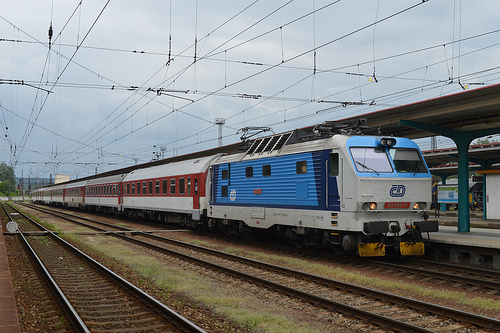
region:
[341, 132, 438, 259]
The front of a gray and blue train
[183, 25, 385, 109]
A collection of criss-crossing wires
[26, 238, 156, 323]
Railroad tracks seen at an angle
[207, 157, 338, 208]
A blue corrugated train car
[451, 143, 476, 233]
A green metal support post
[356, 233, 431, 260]
Black and yellow "mud-flaps"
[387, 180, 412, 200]
A modern, rounded logo in blue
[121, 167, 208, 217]
A red and white train car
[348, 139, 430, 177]
A windshield with two panes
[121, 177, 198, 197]
A row of dark, square windows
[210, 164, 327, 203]
blue paint on train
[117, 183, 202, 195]
red paint on train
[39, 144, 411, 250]
train on train tracks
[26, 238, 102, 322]
train tracks on ground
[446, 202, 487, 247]
train platform beside tracks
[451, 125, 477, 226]
green paint on pole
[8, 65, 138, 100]
light poles above train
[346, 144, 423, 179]
two windows of train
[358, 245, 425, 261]
two yellow pieces on train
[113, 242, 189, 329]
grass growing between tracks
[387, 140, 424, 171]
window on passenger train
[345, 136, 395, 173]
window on passenger train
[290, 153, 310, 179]
window on passenger train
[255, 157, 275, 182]
window on passenger train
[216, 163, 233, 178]
window on passenger train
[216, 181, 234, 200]
window on passenger train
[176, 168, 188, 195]
window on passenger train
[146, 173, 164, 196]
window on passenger train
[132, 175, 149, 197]
window on passenger train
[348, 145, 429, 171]
windshield of the train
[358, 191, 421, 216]
headlights of the train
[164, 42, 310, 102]
powerlines in the sky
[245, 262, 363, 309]
tracks on the ground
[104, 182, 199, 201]
windows on the train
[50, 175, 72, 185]
building behind the train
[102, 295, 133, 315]
wood on the tracks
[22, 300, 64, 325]
dirt on the ground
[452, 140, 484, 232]
pole for the bridge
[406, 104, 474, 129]
side of the bridge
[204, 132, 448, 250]
blue and white light rail engine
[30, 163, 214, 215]
red and white train cars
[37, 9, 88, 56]
white clouds in blue sky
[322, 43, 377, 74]
white clouds in blue sky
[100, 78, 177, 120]
white clouds in blue sky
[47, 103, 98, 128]
white clouds in blue sky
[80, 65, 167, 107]
white clouds in blue sky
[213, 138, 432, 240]
train is blue and white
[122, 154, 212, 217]
train car is red and white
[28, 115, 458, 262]
train is at the station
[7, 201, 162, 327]
railroad ties and rails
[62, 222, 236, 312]
grass between railroad tracks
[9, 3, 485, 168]
suspended power cables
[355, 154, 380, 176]
windshield wiper is black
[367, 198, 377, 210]
light is circular and turned on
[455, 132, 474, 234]
support column is green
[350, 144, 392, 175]
windshield is square